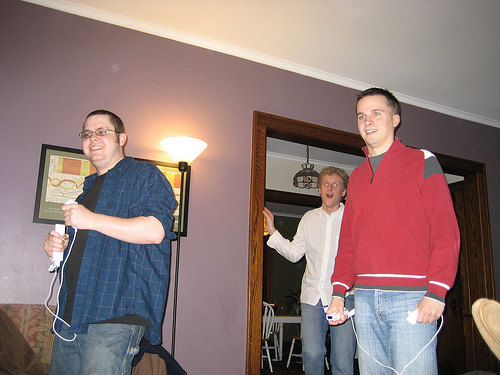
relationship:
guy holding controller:
[48, 109, 179, 374] [54, 223, 65, 268]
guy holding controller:
[326, 88, 460, 373] [328, 309, 352, 324]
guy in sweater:
[326, 88, 460, 373] [331, 144, 460, 300]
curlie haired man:
[319, 166, 348, 186] [263, 165, 355, 373]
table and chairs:
[265, 317, 308, 363] [264, 298, 277, 372]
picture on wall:
[33, 141, 192, 241] [1, 0, 266, 373]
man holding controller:
[48, 109, 179, 374] [54, 223, 65, 268]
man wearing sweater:
[326, 88, 460, 373] [331, 144, 460, 300]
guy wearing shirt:
[48, 109, 179, 374] [60, 156, 175, 338]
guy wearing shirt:
[48, 109, 179, 374] [49, 156, 179, 345]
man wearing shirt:
[326, 88, 460, 373] [365, 151, 388, 174]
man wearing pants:
[263, 165, 355, 373] [300, 295, 357, 374]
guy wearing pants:
[48, 109, 179, 374] [51, 319, 146, 374]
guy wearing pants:
[326, 88, 460, 373] [355, 286, 441, 373]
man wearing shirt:
[263, 165, 355, 373] [271, 203, 344, 305]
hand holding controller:
[326, 295, 347, 325] [328, 309, 352, 324]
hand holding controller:
[45, 231, 69, 257] [54, 223, 65, 268]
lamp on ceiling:
[295, 142, 320, 192] [270, 137, 367, 179]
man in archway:
[263, 165, 355, 373] [248, 108, 494, 374]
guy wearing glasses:
[48, 109, 179, 374] [80, 126, 115, 140]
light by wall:
[162, 134, 207, 170] [1, 0, 266, 373]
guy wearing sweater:
[326, 88, 460, 373] [331, 144, 460, 300]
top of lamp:
[162, 134, 207, 170] [165, 135, 209, 364]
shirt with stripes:
[327, 135, 466, 306] [315, 260, 449, 303]